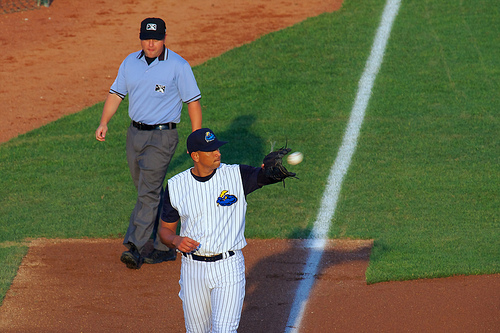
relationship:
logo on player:
[218, 189, 240, 210] [151, 125, 300, 330]